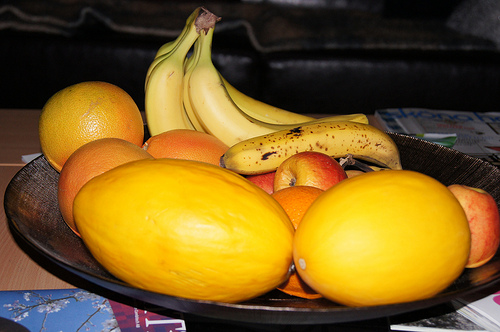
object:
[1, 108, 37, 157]
table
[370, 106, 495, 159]
magazine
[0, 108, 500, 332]
table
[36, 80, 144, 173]
fruit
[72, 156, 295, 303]
fruit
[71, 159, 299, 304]
food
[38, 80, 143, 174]
orange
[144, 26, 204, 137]
banana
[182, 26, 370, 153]
banana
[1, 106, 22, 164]
table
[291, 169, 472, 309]
melon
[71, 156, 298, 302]
melon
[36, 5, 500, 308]
fruit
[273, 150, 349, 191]
apple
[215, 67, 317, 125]
bananas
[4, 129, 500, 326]
bowl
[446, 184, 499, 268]
apple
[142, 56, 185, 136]
bananas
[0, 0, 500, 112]
couch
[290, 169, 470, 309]
fruit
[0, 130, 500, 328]
plate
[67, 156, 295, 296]
light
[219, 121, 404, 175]
banana